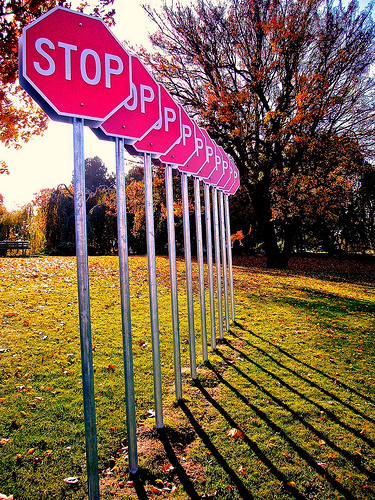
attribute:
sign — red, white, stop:
[29, 19, 157, 127]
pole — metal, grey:
[62, 156, 124, 316]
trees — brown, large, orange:
[225, 36, 349, 192]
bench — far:
[13, 234, 36, 262]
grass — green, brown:
[260, 297, 325, 363]